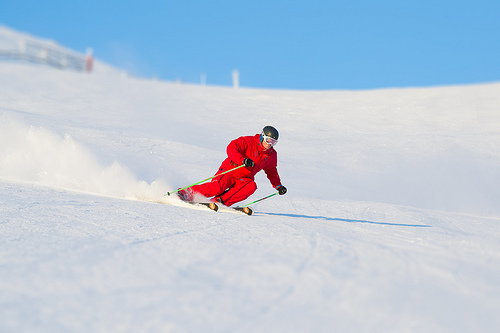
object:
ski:
[230, 205, 254, 216]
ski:
[183, 200, 219, 212]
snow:
[0, 59, 499, 333]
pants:
[176, 168, 259, 208]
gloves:
[275, 184, 288, 196]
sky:
[0, 0, 499, 91]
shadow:
[253, 208, 434, 227]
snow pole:
[235, 191, 279, 208]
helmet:
[261, 124, 279, 149]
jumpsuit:
[176, 134, 284, 209]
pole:
[158, 162, 253, 197]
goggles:
[260, 134, 277, 147]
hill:
[0, 59, 499, 332]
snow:
[0, 198, 500, 330]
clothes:
[210, 132, 282, 191]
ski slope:
[0, 63, 499, 333]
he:
[174, 125, 286, 207]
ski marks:
[130, 208, 248, 247]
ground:
[1, 63, 499, 331]